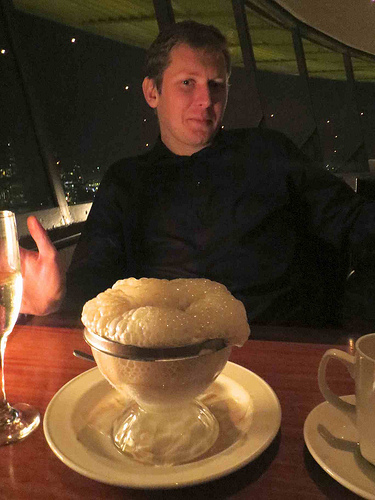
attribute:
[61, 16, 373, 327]
man — sitting, looking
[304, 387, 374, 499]
plate — small, white, light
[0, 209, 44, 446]
glass — big, tall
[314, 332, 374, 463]
cup — white, sitting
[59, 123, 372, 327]
shirt — black, dark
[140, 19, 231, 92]
hair — brown, dark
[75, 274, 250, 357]
foam — spilling, light, large, white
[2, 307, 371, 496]
table — wide, wooden, large, brown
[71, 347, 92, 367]
spoon — silver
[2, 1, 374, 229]
window — round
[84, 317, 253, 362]
rim — silver